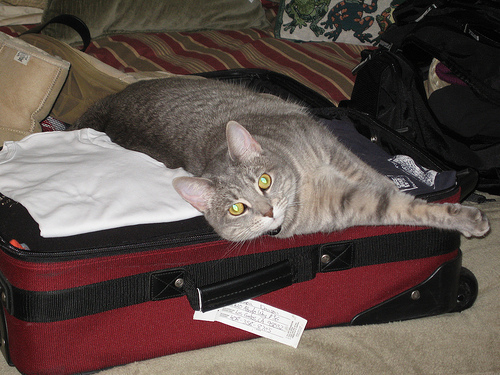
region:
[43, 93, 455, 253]
A cat is on top of a suitcase.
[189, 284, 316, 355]
A white tag is on a suitcase.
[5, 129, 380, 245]
A grey cat is on top of a white shirt.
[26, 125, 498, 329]
A red suitcase is under a cat.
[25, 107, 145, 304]
A suitcase has clothes inside.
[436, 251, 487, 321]
A suitcase has black wheel.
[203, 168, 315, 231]
A cat has yellow eyes.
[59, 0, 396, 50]
Pillows are behind the cat.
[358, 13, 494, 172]
A black bag is next to a suitcase.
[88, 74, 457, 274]
A cat took over a suitcase.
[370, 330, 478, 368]
a dark beige carpet.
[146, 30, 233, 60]
a burgundy green and beige blanket.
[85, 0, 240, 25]
a dark grey pillow.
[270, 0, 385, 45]
a green white and pink pillow with frogs.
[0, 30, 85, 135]
a beige pair of boots.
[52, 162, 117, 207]
a all white tea shirt.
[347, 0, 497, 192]
a big black open back pack.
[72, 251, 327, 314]
a burgundy and black suit case.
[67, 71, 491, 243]
a beautiful grey with stripes cat.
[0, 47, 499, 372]
a beautiful adult cat is laying on the suitcase.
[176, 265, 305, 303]
black handle on suitcase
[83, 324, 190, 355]
red color on suitcase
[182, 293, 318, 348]
white name tag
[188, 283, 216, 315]
string on white name tag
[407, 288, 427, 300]
small screw on suitcase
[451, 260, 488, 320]
black wheel on suitcase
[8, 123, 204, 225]
folded white tee shirt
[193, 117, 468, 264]
cat laying on suitcase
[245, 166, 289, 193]
mesmerizing green eyes on cat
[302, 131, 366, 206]
cat with gray fur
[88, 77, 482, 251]
A gray cat laying on a suitcase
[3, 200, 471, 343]
A red suitcase with black trim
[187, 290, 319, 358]
Name identification tag on handle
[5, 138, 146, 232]
A folded white shirt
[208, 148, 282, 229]
A gray cat with green eyes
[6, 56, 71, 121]
A light brown boot on left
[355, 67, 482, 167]
A black bag on the right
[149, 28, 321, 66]
Burgundy and green striped fabric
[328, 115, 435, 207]
A navy blue piece of clothing with white design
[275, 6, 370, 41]
A frog print pillow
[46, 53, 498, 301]
the cat is on the bag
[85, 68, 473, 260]
the cat is grey in colour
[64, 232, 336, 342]
the bag is red in colour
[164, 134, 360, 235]
its pupils are green in colour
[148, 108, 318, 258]
its eyes are open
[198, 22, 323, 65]
the sheet is red in colour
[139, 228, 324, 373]
the bag has a tag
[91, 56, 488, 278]
the cat is stretching itself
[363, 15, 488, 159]
the bag is black in colour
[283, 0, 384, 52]
the wall is white in colour